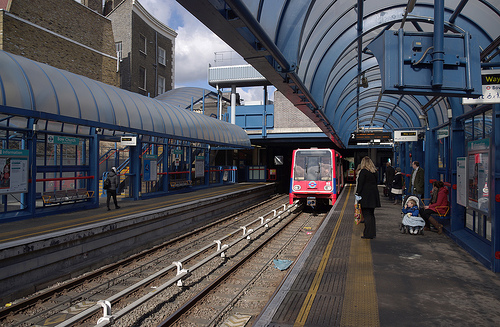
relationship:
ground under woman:
[291, 171, 478, 324] [354, 152, 390, 236]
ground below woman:
[291, 171, 478, 324] [354, 152, 390, 236]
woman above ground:
[354, 152, 390, 236] [291, 171, 478, 324]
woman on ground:
[354, 152, 390, 236] [291, 171, 478, 324]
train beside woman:
[282, 141, 343, 211] [354, 152, 390, 236]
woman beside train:
[354, 152, 390, 236] [282, 141, 343, 211]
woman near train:
[354, 152, 390, 236] [282, 141, 343, 211]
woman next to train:
[354, 152, 390, 236] [282, 141, 343, 211]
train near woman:
[282, 141, 343, 211] [354, 152, 390, 236]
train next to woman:
[282, 141, 343, 211] [354, 152, 390, 236]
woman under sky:
[354, 152, 390, 236] [129, 2, 454, 114]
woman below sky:
[354, 152, 390, 236] [129, 2, 454, 114]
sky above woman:
[129, 2, 454, 114] [354, 152, 390, 236]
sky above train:
[129, 2, 454, 114] [282, 141, 343, 211]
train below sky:
[282, 141, 343, 211] [129, 2, 454, 114]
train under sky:
[282, 141, 343, 211] [129, 2, 454, 114]